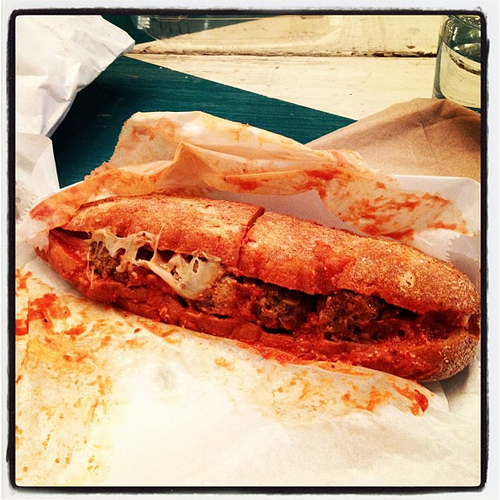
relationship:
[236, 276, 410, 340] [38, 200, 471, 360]
meat in sandwich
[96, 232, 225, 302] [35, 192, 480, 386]
cheese in bread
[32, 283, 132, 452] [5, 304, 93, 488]
stains on surface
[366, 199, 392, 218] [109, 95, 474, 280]
sauce staining paper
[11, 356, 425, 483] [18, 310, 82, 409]
paper has sauce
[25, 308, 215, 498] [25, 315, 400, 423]
paper has sauce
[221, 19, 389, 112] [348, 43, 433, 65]
surface has stains